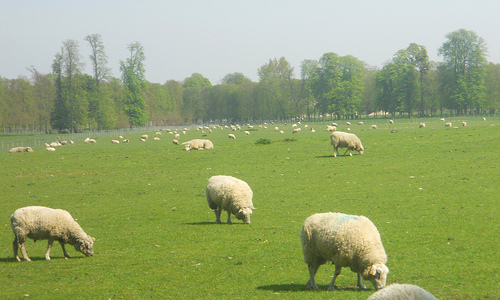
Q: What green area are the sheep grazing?
A: A pasture.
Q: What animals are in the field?
A: Sheep.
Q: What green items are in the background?
A: Trees.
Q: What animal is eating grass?
A: A sheep.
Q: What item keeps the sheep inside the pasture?
A: A fence.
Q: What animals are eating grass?
A: Sheep.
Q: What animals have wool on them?
A: Sheep.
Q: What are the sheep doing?
A: Eating grass.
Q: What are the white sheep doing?
A: Eating grass.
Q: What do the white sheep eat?
A: Green grass.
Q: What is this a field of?
A: A field of sheep.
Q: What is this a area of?
A: A area with sheep.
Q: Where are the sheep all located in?
A: A field.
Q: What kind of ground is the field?
A: A green grass filled field.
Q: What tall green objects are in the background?
A: Group of green trees.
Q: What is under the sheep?
A: Green grass.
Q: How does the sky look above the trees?
A: Grey.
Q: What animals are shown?
A: Sheep.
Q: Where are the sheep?
A: In a field.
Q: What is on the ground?
A: Grass.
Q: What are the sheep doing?
A: Eating.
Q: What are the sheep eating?
A: Grass.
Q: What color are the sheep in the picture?
A: White.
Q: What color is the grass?
A: Green.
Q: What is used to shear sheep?
A: Shears.